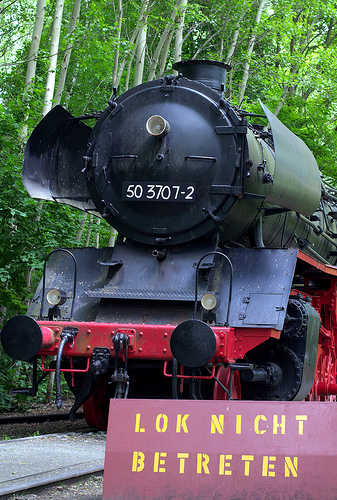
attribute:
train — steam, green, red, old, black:
[15, 78, 332, 410]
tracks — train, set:
[6, 418, 123, 497]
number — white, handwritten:
[120, 172, 205, 216]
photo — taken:
[0, 2, 333, 499]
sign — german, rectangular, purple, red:
[107, 399, 336, 497]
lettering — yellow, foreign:
[124, 411, 303, 478]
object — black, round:
[158, 320, 223, 389]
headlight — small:
[127, 105, 171, 150]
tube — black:
[69, 72, 291, 251]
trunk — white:
[45, 4, 60, 113]